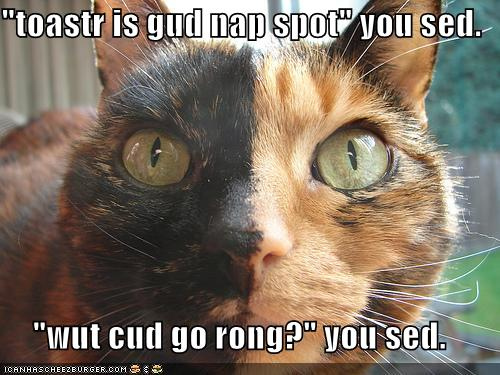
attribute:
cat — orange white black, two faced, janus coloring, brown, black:
[2, 1, 500, 374]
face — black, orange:
[58, 34, 460, 367]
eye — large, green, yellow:
[121, 126, 190, 186]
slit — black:
[150, 136, 163, 168]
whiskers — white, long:
[14, 160, 499, 373]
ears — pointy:
[91, 1, 442, 123]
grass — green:
[446, 248, 499, 343]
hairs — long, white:
[76, 1, 497, 99]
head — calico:
[56, 0, 458, 373]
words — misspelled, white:
[14, 10, 475, 351]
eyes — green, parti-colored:
[121, 124, 391, 191]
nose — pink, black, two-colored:
[200, 221, 293, 288]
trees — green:
[426, 0, 498, 151]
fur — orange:
[56, 201, 462, 373]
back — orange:
[0, 104, 92, 361]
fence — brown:
[444, 149, 499, 248]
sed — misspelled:
[422, 8, 475, 38]